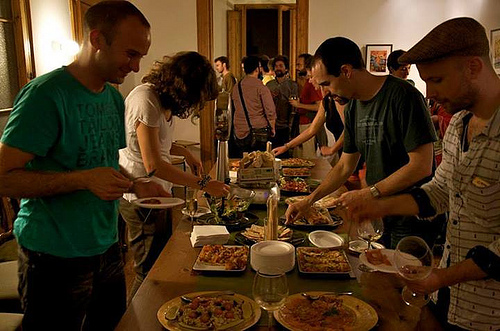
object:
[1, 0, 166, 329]
people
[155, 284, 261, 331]
food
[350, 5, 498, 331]
people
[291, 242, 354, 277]
food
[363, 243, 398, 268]
food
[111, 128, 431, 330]
buffet table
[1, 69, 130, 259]
t-shirt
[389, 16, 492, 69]
hat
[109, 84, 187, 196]
shirt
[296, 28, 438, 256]
man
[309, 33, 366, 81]
dark hair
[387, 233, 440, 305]
wine glass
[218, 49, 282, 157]
people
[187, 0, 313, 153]
doorway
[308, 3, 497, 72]
wall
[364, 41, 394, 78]
paintings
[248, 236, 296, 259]
plates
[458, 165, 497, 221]
shirt pocket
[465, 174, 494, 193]
cigarettes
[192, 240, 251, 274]
serving dishes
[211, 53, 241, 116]
people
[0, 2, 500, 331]
room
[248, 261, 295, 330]
goblet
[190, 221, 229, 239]
paper napkins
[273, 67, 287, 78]
mustache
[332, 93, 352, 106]
beard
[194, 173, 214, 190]
bracelet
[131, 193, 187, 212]
plate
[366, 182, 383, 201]
wrist watch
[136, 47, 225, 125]
wavy hair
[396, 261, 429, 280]
wine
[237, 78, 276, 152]
shoulder bag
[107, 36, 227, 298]
lady